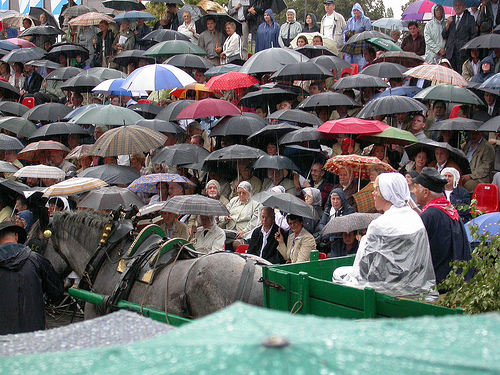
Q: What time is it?
A: Daytime.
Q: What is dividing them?
A: Green fence.